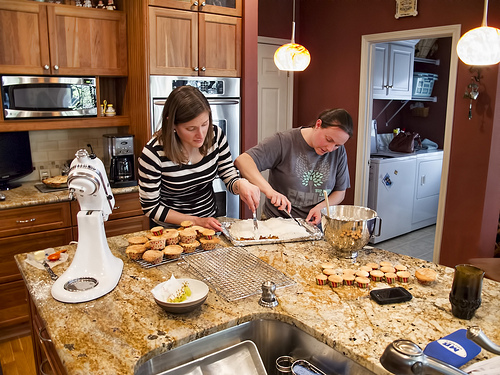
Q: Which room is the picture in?
A: It is at the kitchen.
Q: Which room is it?
A: It is a kitchen.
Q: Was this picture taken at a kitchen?
A: Yes, it was taken in a kitchen.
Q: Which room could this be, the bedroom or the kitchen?
A: It is the kitchen.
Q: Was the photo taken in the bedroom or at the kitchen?
A: It was taken at the kitchen.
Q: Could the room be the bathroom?
A: No, it is the kitchen.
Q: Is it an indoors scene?
A: Yes, it is indoors.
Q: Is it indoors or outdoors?
A: It is indoors.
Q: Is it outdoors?
A: No, it is indoors.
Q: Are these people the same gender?
A: Yes, all the people are female.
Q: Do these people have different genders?
A: No, all the people are female.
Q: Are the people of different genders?
A: No, all the people are female.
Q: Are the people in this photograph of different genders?
A: No, all the people are female.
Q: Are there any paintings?
A: No, there are no paintings.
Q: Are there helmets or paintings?
A: No, there are no paintings or helmets.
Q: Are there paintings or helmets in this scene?
A: No, there are no paintings or helmets.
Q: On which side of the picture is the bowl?
A: The bowl is on the right of the image.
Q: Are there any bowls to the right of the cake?
A: Yes, there is a bowl to the right of the cake.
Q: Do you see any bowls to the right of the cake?
A: Yes, there is a bowl to the right of the cake.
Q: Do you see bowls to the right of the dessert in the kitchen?
A: Yes, there is a bowl to the right of the cake.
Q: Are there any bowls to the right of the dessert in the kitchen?
A: Yes, there is a bowl to the right of the cake.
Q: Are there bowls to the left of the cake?
A: No, the bowl is to the right of the cake.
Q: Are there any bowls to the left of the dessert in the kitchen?
A: No, the bowl is to the right of the cake.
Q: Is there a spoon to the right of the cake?
A: No, there is a bowl to the right of the cake.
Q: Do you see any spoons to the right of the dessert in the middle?
A: No, there is a bowl to the right of the cake.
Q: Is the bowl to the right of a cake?
A: Yes, the bowl is to the right of a cake.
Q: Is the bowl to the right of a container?
A: No, the bowl is to the right of a cake.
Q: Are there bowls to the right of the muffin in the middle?
A: Yes, there is a bowl to the right of the muffin.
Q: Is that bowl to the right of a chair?
A: No, the bowl is to the right of a muffin.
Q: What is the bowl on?
A: The bowl is on the counter.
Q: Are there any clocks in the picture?
A: No, there are no clocks.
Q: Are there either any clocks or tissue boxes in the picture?
A: No, there are no clocks or tissue boxes.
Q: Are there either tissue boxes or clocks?
A: No, there are no clocks or tissue boxes.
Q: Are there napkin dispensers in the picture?
A: No, there are no napkin dispensers.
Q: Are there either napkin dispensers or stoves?
A: No, there are no napkin dispensers or stoves.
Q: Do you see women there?
A: Yes, there is a woman.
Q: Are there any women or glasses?
A: Yes, there is a woman.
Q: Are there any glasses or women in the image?
A: Yes, there is a woman.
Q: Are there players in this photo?
A: No, there are no players.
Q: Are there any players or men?
A: No, there are no players or men.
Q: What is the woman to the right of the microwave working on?
A: The woman is working on the counter.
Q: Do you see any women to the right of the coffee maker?
A: Yes, there is a woman to the right of the coffee maker.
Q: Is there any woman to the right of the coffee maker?
A: Yes, there is a woman to the right of the coffee maker.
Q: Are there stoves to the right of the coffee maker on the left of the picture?
A: No, there is a woman to the right of the coffee machine.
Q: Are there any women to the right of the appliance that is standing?
A: Yes, there is a woman to the right of the mixer.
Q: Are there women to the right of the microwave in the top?
A: Yes, there is a woman to the right of the microwave.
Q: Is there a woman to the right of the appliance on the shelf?
A: Yes, there is a woman to the right of the microwave.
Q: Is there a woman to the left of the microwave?
A: No, the woman is to the right of the microwave.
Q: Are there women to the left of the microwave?
A: No, the woman is to the right of the microwave.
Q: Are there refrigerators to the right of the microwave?
A: No, there is a woman to the right of the microwave.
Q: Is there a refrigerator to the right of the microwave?
A: No, there is a woman to the right of the microwave.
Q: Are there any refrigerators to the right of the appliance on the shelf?
A: No, there is a woman to the right of the microwave.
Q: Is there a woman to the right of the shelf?
A: Yes, there is a woman to the right of the shelf.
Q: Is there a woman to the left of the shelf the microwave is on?
A: No, the woman is to the right of the shelf.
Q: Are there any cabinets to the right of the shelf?
A: No, there is a woman to the right of the shelf.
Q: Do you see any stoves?
A: No, there are no stoves.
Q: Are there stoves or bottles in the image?
A: No, there are no stoves or bottles.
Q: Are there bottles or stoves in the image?
A: No, there are no stoves or bottles.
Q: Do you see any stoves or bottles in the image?
A: No, there are no stoves or bottles.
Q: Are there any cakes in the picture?
A: Yes, there is a cake.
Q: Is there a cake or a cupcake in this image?
A: Yes, there is a cake.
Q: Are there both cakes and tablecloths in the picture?
A: No, there is a cake but no tablecloths.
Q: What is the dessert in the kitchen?
A: The dessert is a cake.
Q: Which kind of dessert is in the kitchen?
A: The dessert is a cake.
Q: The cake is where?
A: The cake is in the kitchen.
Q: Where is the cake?
A: The cake is in the kitchen.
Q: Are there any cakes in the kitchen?
A: Yes, there is a cake in the kitchen.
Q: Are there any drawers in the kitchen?
A: No, there is a cake in the kitchen.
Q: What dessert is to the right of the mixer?
A: The dessert is a cake.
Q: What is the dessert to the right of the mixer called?
A: The dessert is a cake.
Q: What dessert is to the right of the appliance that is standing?
A: The dessert is a cake.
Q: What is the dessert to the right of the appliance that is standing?
A: The dessert is a cake.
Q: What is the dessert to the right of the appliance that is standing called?
A: The dessert is a cake.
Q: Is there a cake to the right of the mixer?
A: Yes, there is a cake to the right of the mixer.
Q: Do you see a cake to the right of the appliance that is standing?
A: Yes, there is a cake to the right of the mixer.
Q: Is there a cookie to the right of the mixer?
A: No, there is a cake to the right of the mixer.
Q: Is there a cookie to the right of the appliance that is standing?
A: No, there is a cake to the right of the mixer.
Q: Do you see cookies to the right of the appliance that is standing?
A: No, there is a cake to the right of the mixer.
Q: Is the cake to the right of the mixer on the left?
A: Yes, the cake is to the right of the mixer.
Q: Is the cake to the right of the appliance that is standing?
A: Yes, the cake is to the right of the mixer.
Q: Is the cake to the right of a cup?
A: No, the cake is to the right of the mixer.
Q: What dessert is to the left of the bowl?
A: The dessert is a cake.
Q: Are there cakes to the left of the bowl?
A: Yes, there is a cake to the left of the bowl.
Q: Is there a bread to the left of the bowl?
A: No, there is a cake to the left of the bowl.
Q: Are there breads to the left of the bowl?
A: No, there is a cake to the left of the bowl.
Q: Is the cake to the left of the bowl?
A: Yes, the cake is to the left of the bowl.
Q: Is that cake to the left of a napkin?
A: No, the cake is to the left of the bowl.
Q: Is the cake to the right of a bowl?
A: No, the cake is to the left of a bowl.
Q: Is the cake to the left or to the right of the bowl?
A: The cake is to the left of the bowl.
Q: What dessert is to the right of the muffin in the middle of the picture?
A: The dessert is a cake.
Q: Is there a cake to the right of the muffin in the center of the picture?
A: Yes, there is a cake to the right of the muffin.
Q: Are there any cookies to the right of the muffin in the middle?
A: No, there is a cake to the right of the muffin.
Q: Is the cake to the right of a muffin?
A: Yes, the cake is to the right of a muffin.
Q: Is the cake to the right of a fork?
A: No, the cake is to the right of a muffin.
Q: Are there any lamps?
A: Yes, there is a lamp.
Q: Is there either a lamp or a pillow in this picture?
A: Yes, there is a lamp.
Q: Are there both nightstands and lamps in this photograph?
A: No, there is a lamp but no nightstands.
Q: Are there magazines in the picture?
A: No, there are no magazines.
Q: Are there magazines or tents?
A: No, there are no magazines or tents.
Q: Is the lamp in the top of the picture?
A: Yes, the lamp is in the top of the image.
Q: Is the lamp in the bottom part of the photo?
A: No, the lamp is in the top of the image.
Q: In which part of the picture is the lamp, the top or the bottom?
A: The lamp is in the top of the image.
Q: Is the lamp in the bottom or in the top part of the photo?
A: The lamp is in the top of the image.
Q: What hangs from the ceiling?
A: The lamp hangs from the ceiling.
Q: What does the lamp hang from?
A: The lamp hangs from the ceiling.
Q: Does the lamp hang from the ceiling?
A: Yes, the lamp hangs from the ceiling.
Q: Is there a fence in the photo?
A: No, there are no fences.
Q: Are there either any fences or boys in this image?
A: No, there are no fences or boys.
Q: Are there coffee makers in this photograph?
A: Yes, there is a coffee maker.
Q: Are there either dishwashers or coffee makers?
A: Yes, there is a coffee maker.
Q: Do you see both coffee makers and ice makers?
A: No, there is a coffee maker but no ice makers.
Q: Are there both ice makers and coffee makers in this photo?
A: No, there is a coffee maker but no ice makers.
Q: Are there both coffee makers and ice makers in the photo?
A: No, there is a coffee maker but no ice makers.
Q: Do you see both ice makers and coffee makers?
A: No, there is a coffee maker but no ice makers.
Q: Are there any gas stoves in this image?
A: No, there are no gas stoves.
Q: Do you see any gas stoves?
A: No, there are no gas stoves.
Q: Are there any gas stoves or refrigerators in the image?
A: No, there are no gas stoves or refrigerators.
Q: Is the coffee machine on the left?
A: Yes, the coffee machine is on the left of the image.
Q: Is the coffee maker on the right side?
A: No, the coffee maker is on the left of the image.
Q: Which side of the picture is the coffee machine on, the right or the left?
A: The coffee machine is on the left of the image.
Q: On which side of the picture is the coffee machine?
A: The coffee machine is on the left of the image.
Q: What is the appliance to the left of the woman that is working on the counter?
A: The appliance is a coffee maker.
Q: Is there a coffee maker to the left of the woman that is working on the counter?
A: Yes, there is a coffee maker to the left of the woman.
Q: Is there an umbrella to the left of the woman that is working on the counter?
A: No, there is a coffee maker to the left of the woman.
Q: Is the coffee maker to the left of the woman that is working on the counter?
A: Yes, the coffee maker is to the left of the woman.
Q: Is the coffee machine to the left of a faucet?
A: No, the coffee machine is to the left of the woman.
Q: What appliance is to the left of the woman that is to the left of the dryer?
A: The appliance is a coffee maker.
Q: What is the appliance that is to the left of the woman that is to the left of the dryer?
A: The appliance is a coffee maker.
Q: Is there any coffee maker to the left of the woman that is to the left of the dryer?
A: Yes, there is a coffee maker to the left of the woman.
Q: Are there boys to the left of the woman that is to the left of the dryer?
A: No, there is a coffee maker to the left of the woman.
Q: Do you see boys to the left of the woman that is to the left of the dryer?
A: No, there is a coffee maker to the left of the woman.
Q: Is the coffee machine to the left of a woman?
A: Yes, the coffee machine is to the left of a woman.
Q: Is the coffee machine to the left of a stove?
A: No, the coffee machine is to the left of a woman.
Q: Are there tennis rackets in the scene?
A: No, there are no tennis rackets.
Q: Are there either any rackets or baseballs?
A: No, there are no rackets or baseballs.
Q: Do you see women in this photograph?
A: Yes, there is a woman.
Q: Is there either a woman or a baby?
A: Yes, there is a woman.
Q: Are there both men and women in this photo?
A: No, there is a woman but no men.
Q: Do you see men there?
A: No, there are no men.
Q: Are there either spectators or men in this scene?
A: No, there are no men or spectators.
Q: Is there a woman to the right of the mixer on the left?
A: Yes, there is a woman to the right of the mixer.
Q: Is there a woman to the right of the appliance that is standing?
A: Yes, there is a woman to the right of the mixer.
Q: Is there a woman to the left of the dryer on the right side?
A: Yes, there is a woman to the left of the dryer.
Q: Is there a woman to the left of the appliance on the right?
A: Yes, there is a woman to the left of the dryer.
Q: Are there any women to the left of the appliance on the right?
A: Yes, there is a woman to the left of the dryer.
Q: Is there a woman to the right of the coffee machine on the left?
A: Yes, there is a woman to the right of the coffee maker.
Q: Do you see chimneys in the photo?
A: No, there are no chimneys.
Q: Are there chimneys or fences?
A: No, there are no chimneys or fences.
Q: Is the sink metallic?
A: Yes, the sink is metallic.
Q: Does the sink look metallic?
A: Yes, the sink is metallic.